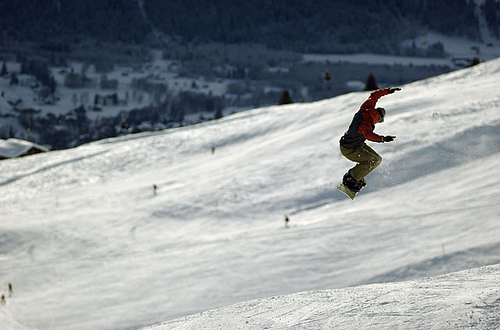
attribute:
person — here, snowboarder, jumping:
[339, 86, 401, 192]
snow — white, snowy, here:
[1, 52, 499, 329]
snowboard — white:
[336, 173, 368, 200]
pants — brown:
[341, 143, 382, 182]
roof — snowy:
[0, 138, 49, 158]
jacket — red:
[341, 87, 389, 149]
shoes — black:
[342, 172, 366, 191]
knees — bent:
[363, 155, 383, 166]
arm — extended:
[361, 86, 401, 109]